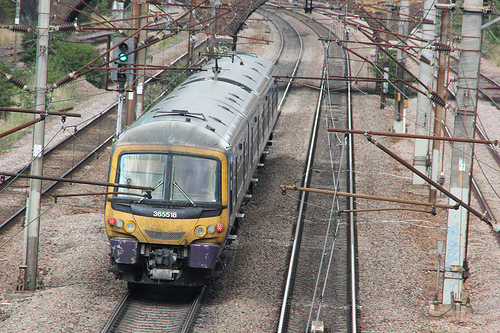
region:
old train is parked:
[103, 53, 278, 295]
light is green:
[107, 35, 134, 84]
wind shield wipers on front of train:
[138, 178, 195, 208]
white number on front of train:
[151, 210, 178, 217]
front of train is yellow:
[103, 143, 230, 245]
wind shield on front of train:
[115, 153, 220, 205]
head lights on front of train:
[107, 218, 222, 238]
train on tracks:
[97, 7, 302, 332]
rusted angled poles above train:
[1, 0, 498, 233]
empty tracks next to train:
[0, 0, 360, 332]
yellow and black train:
[91, 45, 285, 297]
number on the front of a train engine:
[148, 207, 180, 222]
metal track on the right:
[281, 13, 362, 332]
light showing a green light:
[106, 34, 138, 89]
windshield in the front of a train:
[113, 147, 225, 217]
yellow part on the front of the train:
[103, 143, 233, 246]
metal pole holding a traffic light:
[107, 81, 124, 176]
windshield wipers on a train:
[134, 177, 194, 212]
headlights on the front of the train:
[103, 215, 233, 238]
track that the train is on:
[84, 278, 214, 332]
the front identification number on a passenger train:
[147, 208, 180, 223]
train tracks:
[285, 226, 360, 309]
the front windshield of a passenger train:
[110, 147, 225, 214]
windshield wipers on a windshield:
[133, 179, 198, 213]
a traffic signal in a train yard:
[105, 34, 146, 89]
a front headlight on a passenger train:
[187, 222, 211, 242]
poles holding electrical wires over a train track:
[299, 28, 441, 223]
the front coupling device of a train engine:
[138, 244, 186, 282]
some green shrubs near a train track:
[47, 37, 114, 83]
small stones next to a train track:
[365, 237, 422, 314]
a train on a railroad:
[80, 33, 291, 314]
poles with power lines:
[350, 0, 497, 297]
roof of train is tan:
[118, 36, 284, 175]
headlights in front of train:
[101, 212, 223, 242]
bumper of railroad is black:
[102, 257, 212, 294]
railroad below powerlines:
[163, 6, 360, 72]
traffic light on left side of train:
[103, 35, 138, 95]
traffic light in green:
[102, 30, 135, 98]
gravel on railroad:
[16, 238, 428, 332]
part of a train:
[220, 80, 254, 117]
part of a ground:
[247, 277, 267, 310]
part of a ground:
[242, 261, 268, 300]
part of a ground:
[250, 265, 272, 307]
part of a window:
[168, 155, 188, 199]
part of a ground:
[238, 256, 264, 287]